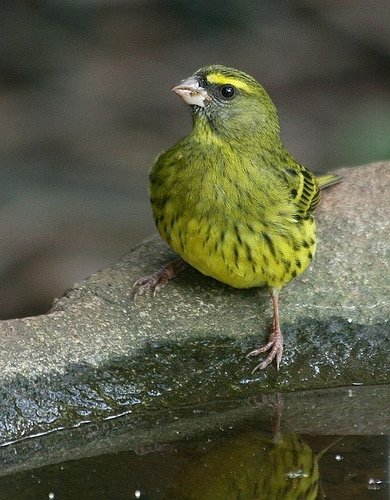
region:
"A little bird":
[121, 60, 339, 374]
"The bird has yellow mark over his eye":
[163, 60, 332, 221]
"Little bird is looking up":
[141, 42, 355, 267]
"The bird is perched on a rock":
[130, 66, 352, 375]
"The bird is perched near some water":
[150, 56, 350, 498]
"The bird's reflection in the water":
[126, 384, 372, 498]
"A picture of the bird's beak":
[164, 56, 214, 111]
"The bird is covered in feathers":
[156, 93, 345, 293]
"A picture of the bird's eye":
[211, 75, 252, 108]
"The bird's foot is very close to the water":
[244, 287, 342, 456]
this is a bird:
[144, 62, 323, 370]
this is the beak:
[171, 76, 208, 112]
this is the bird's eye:
[220, 86, 235, 97]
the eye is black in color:
[223, 85, 234, 98]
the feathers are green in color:
[200, 133, 261, 237]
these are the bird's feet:
[137, 261, 295, 374]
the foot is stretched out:
[250, 291, 287, 373]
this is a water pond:
[205, 407, 381, 498]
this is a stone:
[57, 321, 132, 353]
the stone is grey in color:
[96, 312, 128, 337]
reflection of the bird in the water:
[167, 399, 353, 494]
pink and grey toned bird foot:
[244, 297, 296, 373]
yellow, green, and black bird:
[120, 61, 350, 306]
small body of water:
[6, 387, 388, 498]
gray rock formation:
[1, 213, 389, 420]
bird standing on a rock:
[100, 57, 366, 369]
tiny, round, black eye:
[218, 82, 237, 102]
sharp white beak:
[175, 75, 206, 109]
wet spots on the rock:
[22, 353, 228, 403]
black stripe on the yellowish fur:
[229, 239, 241, 266]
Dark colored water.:
[235, 412, 304, 482]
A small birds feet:
[120, 253, 319, 382]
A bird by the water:
[28, 59, 387, 428]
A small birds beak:
[159, 63, 210, 110]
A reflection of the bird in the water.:
[136, 352, 344, 498]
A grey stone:
[32, 317, 178, 371]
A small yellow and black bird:
[129, 58, 363, 383]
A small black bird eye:
[219, 81, 242, 104]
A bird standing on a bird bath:
[115, 53, 352, 378]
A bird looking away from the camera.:
[123, 42, 349, 384]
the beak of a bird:
[172, 71, 207, 107]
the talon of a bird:
[243, 288, 287, 376]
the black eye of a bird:
[217, 81, 238, 101]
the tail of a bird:
[309, 163, 348, 198]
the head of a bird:
[166, 61, 283, 149]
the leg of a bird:
[268, 288, 285, 335]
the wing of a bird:
[272, 147, 323, 221]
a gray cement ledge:
[0, 157, 389, 444]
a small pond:
[0, 381, 388, 498]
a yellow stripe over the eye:
[205, 70, 256, 97]